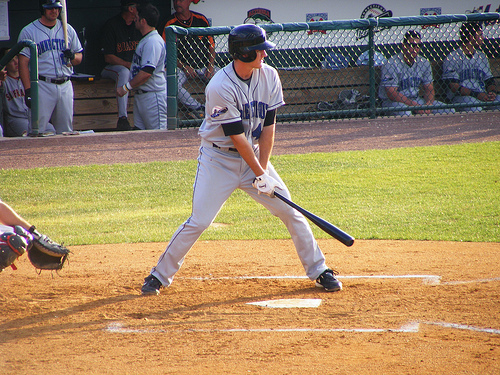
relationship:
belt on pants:
[211, 142, 237, 152] [151, 145, 333, 285]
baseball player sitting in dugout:
[140, 22, 355, 296] [35, 5, 483, 125]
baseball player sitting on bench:
[141, 24, 351, 294] [300, 55, 381, 110]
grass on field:
[0, 139, 497, 246] [2, 112, 493, 371]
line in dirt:
[202, 265, 478, 286] [0, 238, 497, 373]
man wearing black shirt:
[105, 7, 142, 82] [105, 20, 137, 59]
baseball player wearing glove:
[140, 22, 355, 296] [254, 169, 284, 192]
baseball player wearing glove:
[140, 22, 355, 296] [250, 177, 272, 198]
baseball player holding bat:
[140, 22, 355, 296] [271, 186, 358, 247]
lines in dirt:
[107, 264, 499, 342] [0, 238, 497, 373]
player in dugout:
[18, 2, 83, 136] [4, 2, 490, 147]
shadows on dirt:
[1, 285, 322, 341] [0, 238, 497, 373]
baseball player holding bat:
[141, 24, 351, 294] [246, 168, 358, 252]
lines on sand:
[111, 319, 498, 337] [1, 239, 498, 373]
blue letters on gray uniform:
[236, 95, 268, 120] [149, 62, 328, 287]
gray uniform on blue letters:
[445, 46, 499, 108] [459, 65, 487, 85]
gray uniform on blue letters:
[123, 32, 168, 129] [132, 52, 143, 67]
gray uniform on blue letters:
[21, 17, 86, 131] [36, 40, 68, 50]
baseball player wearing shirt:
[140, 22, 355, 296] [186, 75, 313, 154]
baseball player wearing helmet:
[140, 22, 355, 296] [226, 23, 275, 55]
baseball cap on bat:
[228, 24, 277, 54] [274, 181, 356, 247]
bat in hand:
[250, 177, 355, 247] [251, 168, 267, 194]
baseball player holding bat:
[140, 22, 355, 296] [250, 177, 355, 247]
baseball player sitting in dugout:
[382, 28, 451, 113] [4, 2, 490, 147]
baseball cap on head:
[223, 24, 279, 56] [228, 22, 270, 68]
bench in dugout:
[12, 62, 498, 144] [4, 2, 490, 147]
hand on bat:
[255, 173, 285, 198] [272, 189, 357, 252]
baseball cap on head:
[228, 24, 277, 54] [223, 48, 269, 73]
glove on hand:
[23, 233, 72, 273] [29, 230, 59, 248]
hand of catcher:
[29, 230, 59, 248] [0, 190, 74, 291]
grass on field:
[411, 143, 463, 210] [2, 112, 493, 371]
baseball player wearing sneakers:
[140, 22, 355, 296] [129, 251, 373, 328]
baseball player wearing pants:
[140, 22, 355, 296] [151, 145, 333, 285]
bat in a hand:
[250, 177, 355, 247] [255, 175, 285, 197]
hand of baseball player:
[255, 175, 285, 197] [140, 22, 355, 296]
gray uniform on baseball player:
[149, 62, 328, 287] [141, 24, 351, 294]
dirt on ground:
[8, 250, 499, 357] [0, 110, 494, 371]